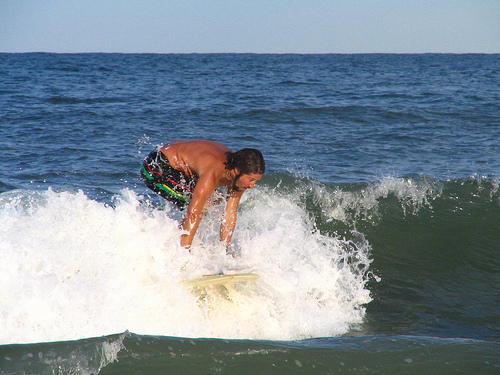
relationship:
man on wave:
[140, 138, 266, 277] [3, 169, 499, 375]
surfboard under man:
[177, 271, 261, 302] [140, 138, 266, 277]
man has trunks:
[140, 138, 266, 277] [141, 149, 196, 212]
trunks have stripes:
[141, 149, 196, 212] [139, 159, 193, 203]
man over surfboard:
[140, 138, 266, 277] [177, 271, 261, 302]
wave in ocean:
[3, 169, 499, 375] [1, 50, 497, 374]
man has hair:
[140, 138, 266, 277] [223, 146, 267, 177]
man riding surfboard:
[140, 138, 266, 277] [177, 271, 261, 302]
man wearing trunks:
[140, 138, 266, 277] [141, 149, 196, 212]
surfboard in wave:
[177, 271, 261, 302] [3, 169, 499, 375]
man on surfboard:
[140, 138, 266, 277] [177, 271, 261, 302]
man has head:
[140, 138, 266, 277] [223, 147, 267, 193]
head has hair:
[223, 147, 267, 193] [223, 146, 267, 177]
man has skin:
[140, 138, 266, 277] [160, 138, 263, 260]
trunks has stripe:
[141, 149, 196, 212] [142, 157, 191, 192]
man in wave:
[140, 138, 266, 277] [3, 169, 499, 375]